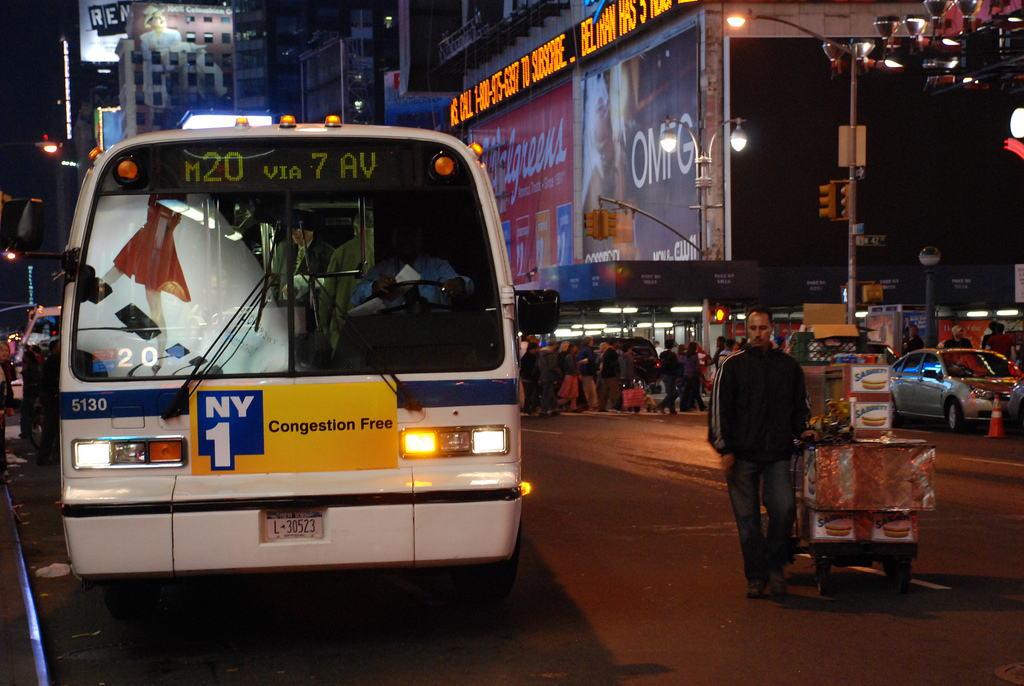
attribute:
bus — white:
[54, 91, 668, 656]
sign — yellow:
[196, 359, 423, 472]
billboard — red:
[429, 55, 680, 256]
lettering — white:
[484, 81, 603, 341]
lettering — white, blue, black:
[233, 392, 365, 470]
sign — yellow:
[108, 323, 480, 490]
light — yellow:
[689, 31, 774, 114]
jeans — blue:
[713, 456, 832, 597]